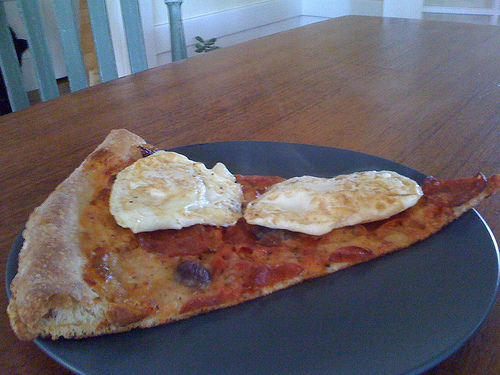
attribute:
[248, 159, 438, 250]
egg —  half ccooked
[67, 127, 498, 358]
plate — blue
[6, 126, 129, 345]
crust —  brown,  baked 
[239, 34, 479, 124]
wood —  brown,  surface,  table's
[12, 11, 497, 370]
dining table —  for dining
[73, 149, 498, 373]
plate — black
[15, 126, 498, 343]
pizza —  a slice, slice,  triangular, brown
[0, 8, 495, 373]
table — wooden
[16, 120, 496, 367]
plate — round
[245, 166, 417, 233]
egg — fried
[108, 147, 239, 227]
egg — fried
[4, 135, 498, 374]
plate —   blue, grey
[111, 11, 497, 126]
table — wooden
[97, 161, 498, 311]
topping —  red